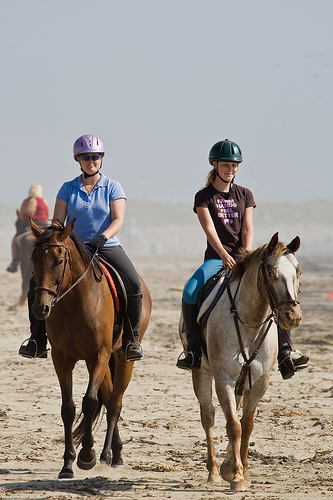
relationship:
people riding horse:
[175, 138, 257, 370] [176, 232, 306, 494]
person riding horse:
[17, 132, 146, 362] [24, 218, 155, 479]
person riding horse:
[8, 183, 51, 270] [5, 208, 50, 308]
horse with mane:
[24, 218, 155, 479] [36, 220, 104, 267]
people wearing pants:
[175, 138, 257, 370] [182, 258, 225, 307]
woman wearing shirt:
[17, 132, 146, 362] [55, 173, 126, 248]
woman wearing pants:
[17, 132, 146, 362] [25, 243, 144, 335]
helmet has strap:
[67, 133, 107, 165] [79, 164, 105, 180]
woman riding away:
[8, 183, 51, 270] [1, 184, 55, 307]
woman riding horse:
[17, 132, 146, 362] [24, 218, 155, 479]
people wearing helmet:
[175, 138, 257, 370] [208, 138, 246, 164]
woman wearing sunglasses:
[17, 132, 146, 362] [75, 152, 104, 163]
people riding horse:
[17, 134, 260, 259] [28, 218, 152, 478]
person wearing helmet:
[17, 132, 146, 362] [67, 133, 107, 165]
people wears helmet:
[175, 138, 257, 370] [208, 138, 246, 164]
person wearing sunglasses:
[17, 132, 146, 362] [75, 152, 104, 163]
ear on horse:
[262, 230, 281, 252] [176, 232, 306, 494]